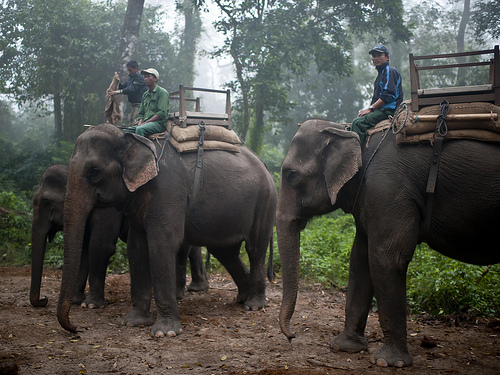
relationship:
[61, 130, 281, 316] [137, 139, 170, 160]
elephant has strap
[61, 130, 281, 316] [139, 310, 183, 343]
elephant has toes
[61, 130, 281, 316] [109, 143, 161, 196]
elephant has ear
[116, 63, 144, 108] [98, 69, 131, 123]
man holding blanket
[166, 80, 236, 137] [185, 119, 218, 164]
seat has rope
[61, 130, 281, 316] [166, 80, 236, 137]
elephant has seat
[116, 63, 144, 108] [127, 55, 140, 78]
man has head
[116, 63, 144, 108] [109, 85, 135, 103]
man has arm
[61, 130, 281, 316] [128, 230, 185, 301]
elephant has leg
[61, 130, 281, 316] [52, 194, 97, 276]
elephant has trunk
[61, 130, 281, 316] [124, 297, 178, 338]
elephant has foot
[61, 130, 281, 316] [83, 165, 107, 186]
elephant has eye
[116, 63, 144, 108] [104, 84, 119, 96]
man has hand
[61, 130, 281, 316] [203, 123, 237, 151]
elephant has sacks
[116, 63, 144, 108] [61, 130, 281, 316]
man riding elephant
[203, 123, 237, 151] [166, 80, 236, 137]
sacks under seat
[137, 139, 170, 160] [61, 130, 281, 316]
strap on elephant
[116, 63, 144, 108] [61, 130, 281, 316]
man on elephant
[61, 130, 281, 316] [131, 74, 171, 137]
elephant has rider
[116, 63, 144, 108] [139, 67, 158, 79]
man wearing hat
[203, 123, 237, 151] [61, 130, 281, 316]
sacks on elephant